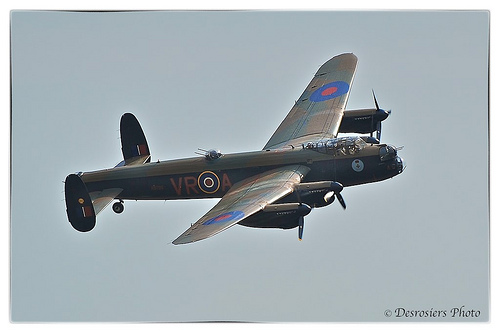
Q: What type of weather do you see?
A: It is cloudy.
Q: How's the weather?
A: It is cloudy.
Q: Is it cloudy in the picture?
A: Yes, it is cloudy.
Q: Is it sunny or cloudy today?
A: It is cloudy.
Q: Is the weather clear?
A: No, it is cloudy.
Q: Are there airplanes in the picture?
A: Yes, there is an airplane.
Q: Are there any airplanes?
A: Yes, there is an airplane.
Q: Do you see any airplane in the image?
A: Yes, there is an airplane.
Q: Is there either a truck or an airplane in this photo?
A: Yes, there is an airplane.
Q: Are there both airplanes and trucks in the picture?
A: No, there is an airplane but no trucks.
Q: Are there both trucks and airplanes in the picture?
A: No, there is an airplane but no trucks.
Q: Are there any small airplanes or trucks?
A: Yes, there is a small airplane.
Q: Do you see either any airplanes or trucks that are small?
A: Yes, the airplane is small.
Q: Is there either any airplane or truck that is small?
A: Yes, the airplane is small.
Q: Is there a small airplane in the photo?
A: Yes, there is a small airplane.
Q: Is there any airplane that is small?
A: Yes, there is an airplane that is small.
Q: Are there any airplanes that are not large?
A: Yes, there is a small airplane.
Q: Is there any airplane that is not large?
A: Yes, there is a small airplane.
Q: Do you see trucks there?
A: No, there are no trucks.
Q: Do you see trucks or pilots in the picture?
A: No, there are no trucks or pilots.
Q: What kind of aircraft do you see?
A: The aircraft is an airplane.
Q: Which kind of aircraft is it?
A: The aircraft is an airplane.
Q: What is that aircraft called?
A: That is an airplane.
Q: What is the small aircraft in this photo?
A: The aircraft is an airplane.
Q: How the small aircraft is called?
A: The aircraft is an airplane.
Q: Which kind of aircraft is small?
A: The aircraft is an airplane.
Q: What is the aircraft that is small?
A: The aircraft is an airplane.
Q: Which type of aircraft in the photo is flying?
A: The aircraft is an airplane.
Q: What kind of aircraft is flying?
A: The aircraft is an airplane.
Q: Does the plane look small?
A: Yes, the plane is small.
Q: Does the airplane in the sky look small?
A: Yes, the airplane is small.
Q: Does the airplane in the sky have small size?
A: Yes, the airplane is small.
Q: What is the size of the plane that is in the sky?
A: The plane is small.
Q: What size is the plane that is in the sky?
A: The plane is small.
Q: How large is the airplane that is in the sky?
A: The plane is small.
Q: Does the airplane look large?
A: No, the airplane is small.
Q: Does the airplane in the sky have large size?
A: No, the airplane is small.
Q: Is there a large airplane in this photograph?
A: No, there is an airplane but it is small.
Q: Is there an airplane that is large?
A: No, there is an airplane but it is small.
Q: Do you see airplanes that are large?
A: No, there is an airplane but it is small.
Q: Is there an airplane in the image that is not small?
A: No, there is an airplane but it is small.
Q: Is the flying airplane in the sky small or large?
A: The airplane is small.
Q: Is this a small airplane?
A: Yes, this is a small airplane.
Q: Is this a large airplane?
A: No, this is a small airplane.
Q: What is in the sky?
A: The airplane is in the sky.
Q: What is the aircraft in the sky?
A: The aircraft is an airplane.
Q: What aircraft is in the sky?
A: The aircraft is an airplane.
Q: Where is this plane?
A: The plane is in the sky.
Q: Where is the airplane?
A: The plane is in the sky.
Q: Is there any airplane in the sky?
A: Yes, there is an airplane in the sky.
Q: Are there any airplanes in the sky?
A: Yes, there is an airplane in the sky.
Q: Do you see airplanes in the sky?
A: Yes, there is an airplane in the sky.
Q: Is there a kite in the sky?
A: No, there is an airplane in the sky.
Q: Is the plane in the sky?
A: Yes, the plane is in the sky.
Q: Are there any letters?
A: Yes, there are letters.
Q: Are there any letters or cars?
A: Yes, there are letters.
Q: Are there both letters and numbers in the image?
A: No, there are letters but no numbers.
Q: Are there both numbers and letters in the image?
A: No, there are letters but no numbers.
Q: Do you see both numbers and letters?
A: No, there are letters but no numbers.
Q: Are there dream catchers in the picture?
A: No, there are no dream catchers.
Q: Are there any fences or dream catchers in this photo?
A: No, there are no dream catchers or fences.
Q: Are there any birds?
A: No, there are no birds.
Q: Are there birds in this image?
A: No, there are no birds.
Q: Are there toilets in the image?
A: No, there are no toilets.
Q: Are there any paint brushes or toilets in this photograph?
A: No, there are no toilets or paint brushes.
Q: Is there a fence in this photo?
A: No, there are no fences.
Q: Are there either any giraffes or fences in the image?
A: No, there are no fences or giraffes.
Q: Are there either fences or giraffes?
A: No, there are no fences or giraffes.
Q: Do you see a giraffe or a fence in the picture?
A: No, there are no fences or giraffes.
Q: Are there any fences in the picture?
A: No, there are no fences.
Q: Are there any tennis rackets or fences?
A: No, there are no fences or tennis rackets.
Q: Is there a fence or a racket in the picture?
A: No, there are no fences or rackets.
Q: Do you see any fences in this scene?
A: No, there are no fences.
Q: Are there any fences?
A: No, there are no fences.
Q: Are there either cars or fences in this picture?
A: No, there are no fences or cars.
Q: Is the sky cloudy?
A: Yes, the sky is cloudy.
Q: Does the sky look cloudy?
A: Yes, the sky is cloudy.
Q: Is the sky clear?
A: No, the sky is cloudy.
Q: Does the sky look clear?
A: No, the sky is cloudy.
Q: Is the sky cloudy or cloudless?
A: The sky is cloudy.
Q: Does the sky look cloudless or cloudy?
A: The sky is cloudy.